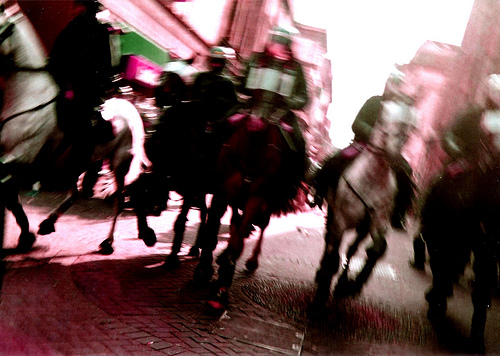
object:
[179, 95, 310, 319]
horse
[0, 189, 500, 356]
blocks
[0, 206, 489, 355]
ground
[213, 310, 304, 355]
square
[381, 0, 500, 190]
buildings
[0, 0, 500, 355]
picture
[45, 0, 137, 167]
rider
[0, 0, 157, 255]
horse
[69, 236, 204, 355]
circle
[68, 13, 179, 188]
store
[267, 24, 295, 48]
hat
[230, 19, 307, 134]
man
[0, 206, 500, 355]
road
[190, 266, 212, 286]
hoof